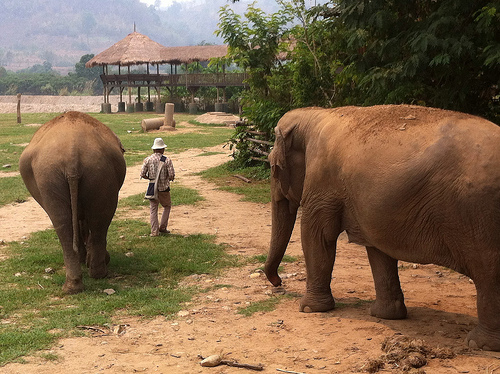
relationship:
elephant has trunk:
[227, 83, 492, 334] [247, 189, 302, 280]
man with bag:
[125, 130, 179, 250] [142, 157, 166, 200]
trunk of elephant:
[247, 189, 302, 280] [227, 83, 492, 334]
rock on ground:
[244, 259, 262, 286] [129, 272, 243, 365]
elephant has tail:
[227, 83, 492, 334] [52, 149, 104, 243]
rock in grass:
[244, 259, 262, 286] [128, 117, 148, 130]